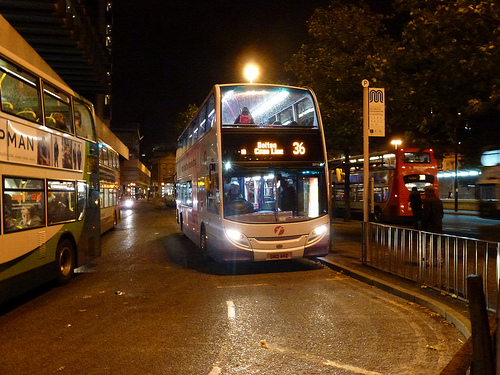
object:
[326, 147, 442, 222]
bus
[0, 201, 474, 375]
street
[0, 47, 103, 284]
bus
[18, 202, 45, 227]
passengers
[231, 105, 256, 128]
person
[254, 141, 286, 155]
destiantion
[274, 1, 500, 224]
trees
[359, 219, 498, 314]
railing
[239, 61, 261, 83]
street light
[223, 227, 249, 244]
headlights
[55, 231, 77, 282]
tires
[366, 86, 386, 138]
sign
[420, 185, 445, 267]
people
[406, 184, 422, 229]
people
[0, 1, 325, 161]
sky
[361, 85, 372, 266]
pole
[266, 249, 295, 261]
license plate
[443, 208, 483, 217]
sidewalk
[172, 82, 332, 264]
bus